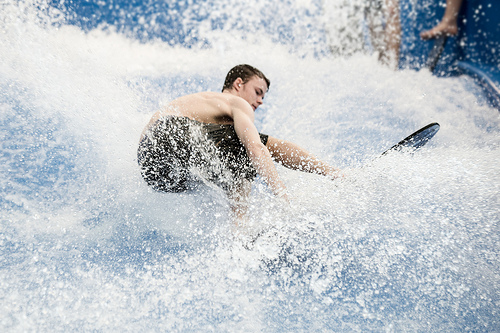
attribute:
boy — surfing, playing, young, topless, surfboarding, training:
[138, 57, 319, 185]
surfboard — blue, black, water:
[262, 112, 433, 169]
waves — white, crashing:
[11, 14, 473, 266]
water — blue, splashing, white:
[2, 1, 490, 332]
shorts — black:
[146, 120, 250, 194]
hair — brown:
[225, 65, 273, 84]